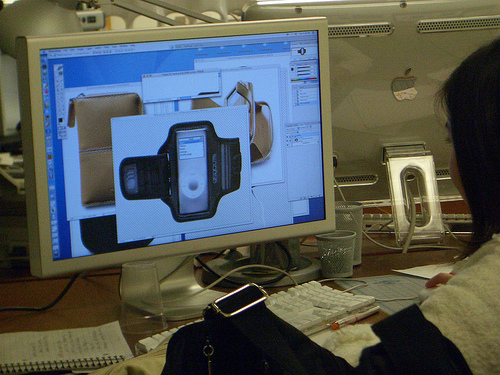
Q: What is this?
A: A monitor.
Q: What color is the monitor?
A: White.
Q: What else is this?
A: A keyboard.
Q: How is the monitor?
A: On.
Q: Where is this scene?
A: At this person's work desk.